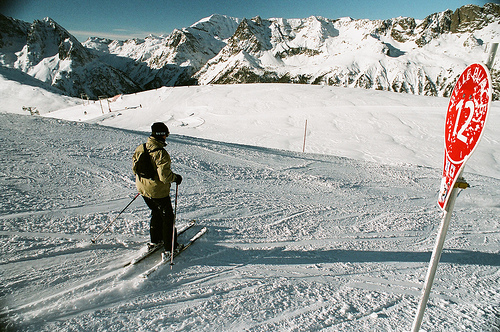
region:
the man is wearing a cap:
[150, 118, 168, 136]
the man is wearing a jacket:
[133, 137, 174, 194]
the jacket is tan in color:
[131, 141, 166, 179]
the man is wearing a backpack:
[135, 135, 176, 201]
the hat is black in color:
[150, 120, 168, 137]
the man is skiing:
[104, 124, 210, 281]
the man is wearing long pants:
[141, 192, 176, 245]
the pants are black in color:
[139, 194, 177, 244]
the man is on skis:
[131, 220, 211, 285]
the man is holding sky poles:
[170, 176, 184, 274]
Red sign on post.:
[413, 53, 487, 329]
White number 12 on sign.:
[447, 94, 478, 149]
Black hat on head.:
[137, 120, 177, 155]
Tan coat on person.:
[127, 117, 202, 272]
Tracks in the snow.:
[20, 262, 160, 323]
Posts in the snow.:
[92, 91, 119, 118]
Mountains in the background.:
[0, 7, 499, 88]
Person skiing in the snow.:
[124, 119, 211, 292]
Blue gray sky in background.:
[75, 3, 162, 23]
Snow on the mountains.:
[292, 20, 360, 85]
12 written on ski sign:
[438, 66, 491, 135]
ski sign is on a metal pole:
[434, 164, 465, 247]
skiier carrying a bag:
[139, 156, 174, 182]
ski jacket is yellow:
[126, 166, 172, 211]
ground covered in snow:
[201, 152, 329, 180]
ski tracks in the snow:
[245, 279, 324, 329]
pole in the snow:
[306, 114, 319, 148]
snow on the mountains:
[227, 9, 343, 92]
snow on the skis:
[127, 252, 173, 273]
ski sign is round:
[448, 68, 488, 148]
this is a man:
[139, 113, 200, 260]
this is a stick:
[164, 186, 182, 270]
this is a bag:
[138, 150, 156, 179]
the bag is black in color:
[136, 156, 149, 169]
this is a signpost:
[431, 60, 493, 197]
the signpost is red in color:
[446, 138, 469, 158]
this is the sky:
[84, 5, 157, 22]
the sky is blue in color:
[92, 8, 135, 38]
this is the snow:
[232, 93, 312, 155]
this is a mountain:
[386, 16, 496, 40]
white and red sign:
[432, 67, 488, 169]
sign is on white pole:
[420, 112, 478, 329]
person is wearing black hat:
[147, 128, 182, 165]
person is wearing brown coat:
[120, 145, 178, 202]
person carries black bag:
[131, 141, 166, 183]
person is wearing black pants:
[136, 179, 162, 249]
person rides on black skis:
[125, 211, 195, 274]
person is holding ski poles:
[112, 188, 180, 263]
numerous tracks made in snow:
[30, 115, 376, 328]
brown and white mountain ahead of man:
[181, 12, 497, 78]